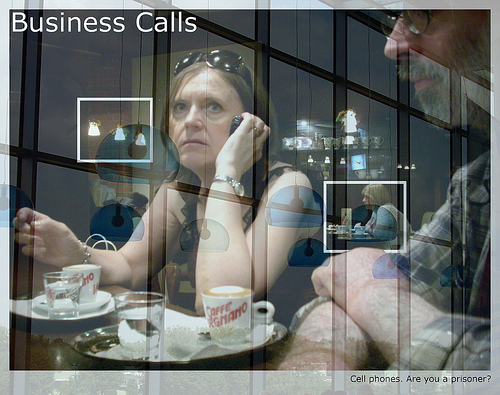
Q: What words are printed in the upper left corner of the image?
A: Business calls.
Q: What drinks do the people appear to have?
A: Coffee and water.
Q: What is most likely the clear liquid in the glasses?
A: Water.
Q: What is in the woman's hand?
A: Phone.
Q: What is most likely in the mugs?
A: Coffee.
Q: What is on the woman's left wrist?
A: Watch.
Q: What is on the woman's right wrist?
A: Bracelets.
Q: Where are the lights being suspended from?
A: Ceiling.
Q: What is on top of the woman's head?
A: Sunglasses.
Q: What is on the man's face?
A: Glasses.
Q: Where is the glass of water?
A: On the table.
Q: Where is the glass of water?
A: In front of the woman.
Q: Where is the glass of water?
A: To the left of the white coffee cup.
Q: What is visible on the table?
A: A glass of water.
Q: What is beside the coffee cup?
A: A glass of water.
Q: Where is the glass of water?
A: On white paper.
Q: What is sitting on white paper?
A: A glass of water.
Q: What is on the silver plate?
A: A glass of water.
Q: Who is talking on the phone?
A: A woman.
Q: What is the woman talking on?
A: Phone.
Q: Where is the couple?
A: Coffee shop.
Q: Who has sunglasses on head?
A: The woman holding the phone.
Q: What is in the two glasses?
A: Water.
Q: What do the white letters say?
A: Business Calls.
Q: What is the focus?
A: Electronic tethering.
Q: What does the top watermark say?
A: Business Calls.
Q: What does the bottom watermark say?
A: Cell phones. Are you a prisoner?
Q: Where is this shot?
A: Restaurant.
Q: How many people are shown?
A: 4.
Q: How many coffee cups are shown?
A: 2.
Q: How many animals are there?
A: 0.